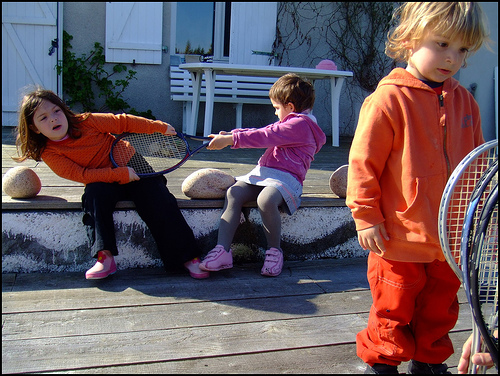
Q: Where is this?
A: This is at the walkway.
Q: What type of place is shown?
A: It is a walkway.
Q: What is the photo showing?
A: It is showing a walkway.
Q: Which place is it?
A: It is a walkway.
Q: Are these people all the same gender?
A: No, they are both male and female.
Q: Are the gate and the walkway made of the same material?
A: Yes, both the gate and the walkway are made of wood.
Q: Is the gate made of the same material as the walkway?
A: Yes, both the gate and the walkway are made of wood.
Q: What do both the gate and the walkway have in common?
A: The material, both the gate and the walkway are wooden.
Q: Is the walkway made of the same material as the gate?
A: Yes, both the walkway and the gate are made of wood.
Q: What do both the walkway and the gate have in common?
A: The material, both the walkway and the gate are wooden.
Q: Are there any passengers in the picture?
A: No, there are no passengers.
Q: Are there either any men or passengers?
A: No, there are no passengers or men.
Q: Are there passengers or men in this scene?
A: No, there are no passengers or men.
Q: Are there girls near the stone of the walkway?
A: Yes, there is a girl near the stone.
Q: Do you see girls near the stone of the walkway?
A: Yes, there is a girl near the stone.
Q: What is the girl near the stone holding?
A: The girl is holding the racket.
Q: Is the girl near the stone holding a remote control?
A: No, the girl is holding the racket.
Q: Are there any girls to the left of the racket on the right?
A: Yes, there is a girl to the left of the tennis racket.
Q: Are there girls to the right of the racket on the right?
A: No, the girl is to the left of the racket.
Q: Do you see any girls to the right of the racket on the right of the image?
A: No, the girl is to the left of the racket.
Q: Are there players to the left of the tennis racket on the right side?
A: No, there is a girl to the left of the tennis racket.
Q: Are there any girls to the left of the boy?
A: Yes, there is a girl to the left of the boy.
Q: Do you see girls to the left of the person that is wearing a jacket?
A: Yes, there is a girl to the left of the boy.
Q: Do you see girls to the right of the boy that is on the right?
A: No, the girl is to the left of the boy.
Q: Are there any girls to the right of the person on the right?
A: No, the girl is to the left of the boy.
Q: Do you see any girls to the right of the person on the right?
A: No, the girl is to the left of the boy.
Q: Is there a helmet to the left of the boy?
A: No, there is a girl to the left of the boy.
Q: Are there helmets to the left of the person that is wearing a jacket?
A: No, there is a girl to the left of the boy.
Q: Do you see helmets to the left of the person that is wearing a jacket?
A: No, there is a girl to the left of the boy.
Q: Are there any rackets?
A: Yes, there is a racket.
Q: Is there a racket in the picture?
A: Yes, there is a racket.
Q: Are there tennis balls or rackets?
A: Yes, there is a racket.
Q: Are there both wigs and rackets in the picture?
A: No, there is a racket but no wigs.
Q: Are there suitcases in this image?
A: No, there are no suitcases.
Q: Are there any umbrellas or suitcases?
A: No, there are no suitcases or umbrellas.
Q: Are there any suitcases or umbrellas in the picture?
A: No, there are no suitcases or umbrellas.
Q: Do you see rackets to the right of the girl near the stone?
A: Yes, there is a racket to the right of the girl.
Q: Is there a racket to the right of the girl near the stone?
A: Yes, there is a racket to the right of the girl.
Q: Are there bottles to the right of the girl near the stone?
A: No, there is a racket to the right of the girl.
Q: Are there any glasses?
A: No, there are no glasses.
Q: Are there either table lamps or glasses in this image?
A: No, there are no glasses or table lamps.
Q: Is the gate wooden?
A: Yes, the gate is wooden.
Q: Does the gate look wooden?
A: Yes, the gate is wooden.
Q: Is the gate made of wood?
A: Yes, the gate is made of wood.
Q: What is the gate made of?
A: The gate is made of wood.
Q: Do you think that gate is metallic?
A: No, the gate is wooden.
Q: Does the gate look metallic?
A: No, the gate is wooden.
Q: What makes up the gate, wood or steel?
A: The gate is made of wood.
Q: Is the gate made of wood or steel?
A: The gate is made of wood.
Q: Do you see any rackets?
A: Yes, there is a racket.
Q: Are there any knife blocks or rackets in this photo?
A: Yes, there is a racket.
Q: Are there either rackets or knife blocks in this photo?
A: Yes, there is a racket.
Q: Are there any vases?
A: No, there are no vases.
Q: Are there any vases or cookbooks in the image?
A: No, there are no vases or cookbooks.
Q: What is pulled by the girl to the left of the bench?
A: The racket is pulled by the girl.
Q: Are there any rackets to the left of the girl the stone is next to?
A: Yes, there is a racket to the left of the girl.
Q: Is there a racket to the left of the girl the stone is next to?
A: Yes, there is a racket to the left of the girl.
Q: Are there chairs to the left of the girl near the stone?
A: No, there is a racket to the left of the girl.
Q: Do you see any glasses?
A: No, there are no glasses.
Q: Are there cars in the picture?
A: No, there are no cars.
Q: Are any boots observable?
A: Yes, there are boots.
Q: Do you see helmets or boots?
A: Yes, there are boots.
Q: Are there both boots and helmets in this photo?
A: No, there are boots but no helmets.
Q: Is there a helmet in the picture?
A: No, there are no helmets.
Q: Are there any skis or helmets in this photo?
A: No, there are no helmets or skis.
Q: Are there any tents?
A: No, there are no tents.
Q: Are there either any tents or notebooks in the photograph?
A: No, there are no tents or notebooks.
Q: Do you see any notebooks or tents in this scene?
A: No, there are no tents or notebooks.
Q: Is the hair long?
A: Yes, the hair is long.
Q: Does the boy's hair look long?
A: Yes, the hair is long.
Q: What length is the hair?
A: The hair is long.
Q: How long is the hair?
A: The hair is long.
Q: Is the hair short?
A: No, the hair is long.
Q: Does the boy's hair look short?
A: No, the hair is long.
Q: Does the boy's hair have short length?
A: No, the hair is long.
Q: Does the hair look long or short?
A: The hair is long.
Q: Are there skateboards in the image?
A: No, there are no skateboards.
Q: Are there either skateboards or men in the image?
A: No, there are no skateboards or men.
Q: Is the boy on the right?
A: Yes, the boy is on the right of the image.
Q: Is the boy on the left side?
A: No, the boy is on the right of the image.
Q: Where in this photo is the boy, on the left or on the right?
A: The boy is on the right of the image.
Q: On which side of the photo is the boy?
A: The boy is on the right of the image.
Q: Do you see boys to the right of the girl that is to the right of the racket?
A: Yes, there is a boy to the right of the girl.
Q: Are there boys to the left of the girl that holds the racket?
A: No, the boy is to the right of the girl.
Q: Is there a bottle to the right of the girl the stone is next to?
A: No, there is a boy to the right of the girl.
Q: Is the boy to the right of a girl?
A: Yes, the boy is to the right of a girl.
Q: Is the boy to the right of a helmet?
A: No, the boy is to the right of a girl.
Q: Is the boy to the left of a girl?
A: No, the boy is to the right of a girl.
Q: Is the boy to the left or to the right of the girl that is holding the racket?
A: The boy is to the right of the girl.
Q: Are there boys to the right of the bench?
A: Yes, there is a boy to the right of the bench.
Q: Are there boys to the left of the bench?
A: No, the boy is to the right of the bench.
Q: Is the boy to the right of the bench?
A: Yes, the boy is to the right of the bench.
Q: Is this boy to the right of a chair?
A: No, the boy is to the right of the bench.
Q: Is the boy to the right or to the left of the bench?
A: The boy is to the right of the bench.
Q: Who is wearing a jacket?
A: The boy is wearing a jacket.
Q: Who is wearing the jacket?
A: The boy is wearing a jacket.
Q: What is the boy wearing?
A: The boy is wearing a jacket.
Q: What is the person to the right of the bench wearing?
A: The boy is wearing a jacket.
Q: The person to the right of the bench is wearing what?
A: The boy is wearing a jacket.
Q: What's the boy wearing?
A: The boy is wearing a jacket.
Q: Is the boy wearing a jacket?
A: Yes, the boy is wearing a jacket.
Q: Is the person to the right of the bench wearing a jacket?
A: Yes, the boy is wearing a jacket.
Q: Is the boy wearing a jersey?
A: No, the boy is wearing a jacket.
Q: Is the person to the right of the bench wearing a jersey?
A: No, the boy is wearing a jacket.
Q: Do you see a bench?
A: Yes, there is a bench.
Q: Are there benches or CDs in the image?
A: Yes, there is a bench.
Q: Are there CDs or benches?
A: Yes, there is a bench.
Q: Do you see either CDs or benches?
A: Yes, there is a bench.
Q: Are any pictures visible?
A: No, there are no pictures.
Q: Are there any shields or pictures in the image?
A: No, there are no pictures or shields.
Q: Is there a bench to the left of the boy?
A: Yes, there is a bench to the left of the boy.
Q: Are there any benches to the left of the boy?
A: Yes, there is a bench to the left of the boy.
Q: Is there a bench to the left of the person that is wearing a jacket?
A: Yes, there is a bench to the left of the boy.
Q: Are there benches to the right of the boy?
A: No, the bench is to the left of the boy.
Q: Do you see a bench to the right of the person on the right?
A: No, the bench is to the left of the boy.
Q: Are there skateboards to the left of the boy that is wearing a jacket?
A: No, there is a bench to the left of the boy.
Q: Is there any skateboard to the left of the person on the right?
A: No, there is a bench to the left of the boy.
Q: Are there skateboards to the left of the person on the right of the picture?
A: No, there is a bench to the left of the boy.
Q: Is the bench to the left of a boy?
A: Yes, the bench is to the left of a boy.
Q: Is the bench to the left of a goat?
A: No, the bench is to the left of a boy.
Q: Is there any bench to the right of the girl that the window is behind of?
A: Yes, there is a bench to the right of the girl.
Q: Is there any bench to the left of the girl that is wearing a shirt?
A: No, the bench is to the right of the girl.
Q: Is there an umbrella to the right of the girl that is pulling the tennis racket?
A: No, there is a bench to the right of the girl.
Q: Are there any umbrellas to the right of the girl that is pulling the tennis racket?
A: No, there is a bench to the right of the girl.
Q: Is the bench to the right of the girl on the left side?
A: Yes, the bench is to the right of the girl.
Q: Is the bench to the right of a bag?
A: No, the bench is to the right of the girl.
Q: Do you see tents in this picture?
A: No, there are no tents.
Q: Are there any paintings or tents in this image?
A: No, there are no tents or paintings.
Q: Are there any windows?
A: Yes, there is a window.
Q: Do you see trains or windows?
A: Yes, there is a window.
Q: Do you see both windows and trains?
A: No, there is a window but no trains.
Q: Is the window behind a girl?
A: Yes, the window is behind a girl.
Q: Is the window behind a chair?
A: No, the window is behind a girl.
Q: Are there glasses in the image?
A: No, there are no glasses.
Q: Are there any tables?
A: Yes, there is a table.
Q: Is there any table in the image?
A: Yes, there is a table.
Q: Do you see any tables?
A: Yes, there is a table.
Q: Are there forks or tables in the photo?
A: Yes, there is a table.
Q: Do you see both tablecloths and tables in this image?
A: No, there is a table but no tablecloths.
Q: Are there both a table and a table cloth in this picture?
A: No, there is a table but no tablecloths.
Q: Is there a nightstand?
A: No, there are no nightstands.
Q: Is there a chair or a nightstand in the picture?
A: No, there are no nightstands or chairs.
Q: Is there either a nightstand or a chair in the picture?
A: No, there are no nightstands or chairs.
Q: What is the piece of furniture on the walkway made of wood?
A: The piece of furniture is a table.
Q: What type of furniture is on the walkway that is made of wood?
A: The piece of furniture is a table.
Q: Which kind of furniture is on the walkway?
A: The piece of furniture is a table.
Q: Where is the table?
A: The table is on the walkway.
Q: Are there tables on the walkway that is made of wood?
A: Yes, there is a table on the walkway.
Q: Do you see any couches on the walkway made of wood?
A: No, there is a table on the walkway.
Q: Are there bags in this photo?
A: No, there are no bags.